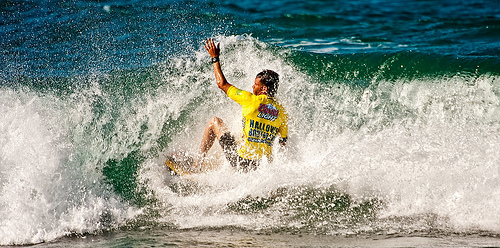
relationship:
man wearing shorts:
[185, 36, 290, 176] [217, 129, 259, 171]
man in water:
[185, 36, 290, 176] [342, 54, 457, 210]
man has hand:
[182, 35, 294, 178] [203, 38, 220, 56]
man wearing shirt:
[185, 36, 290, 176] [225, 85, 289, 159]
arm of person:
[201, 30, 231, 95] [183, 23, 328, 222]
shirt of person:
[225, 84, 295, 174] [183, 23, 328, 222]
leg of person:
[173, 126, 228, 173] [171, 27, 310, 203]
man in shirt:
[185, 36, 290, 176] [230, 84, 298, 164]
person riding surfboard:
[183, 31, 315, 212] [119, 117, 290, 194]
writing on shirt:
[247, 98, 280, 146] [221, 93, 283, 160]